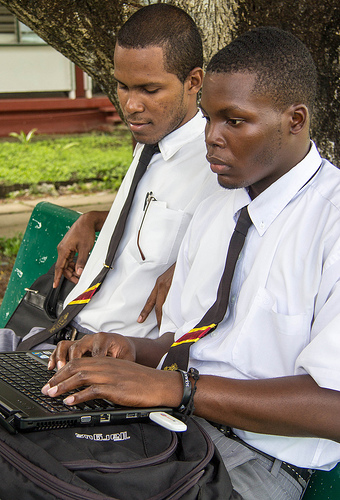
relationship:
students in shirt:
[1, 1, 338, 498] [128, 159, 338, 443]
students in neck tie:
[1, 1, 338, 498] [159, 205, 253, 371]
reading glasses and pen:
[130, 183, 164, 271] [137, 181, 157, 213]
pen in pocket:
[137, 181, 157, 213] [123, 191, 193, 272]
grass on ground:
[1, 136, 118, 194] [3, 132, 121, 189]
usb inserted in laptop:
[143, 392, 194, 460] [7, 291, 175, 492]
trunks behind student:
[0, 0, 336, 153] [38, 24, 339, 498]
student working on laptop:
[55, 50, 336, 462] [2, 285, 161, 454]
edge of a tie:
[134, 297, 232, 395] [150, 204, 243, 374]